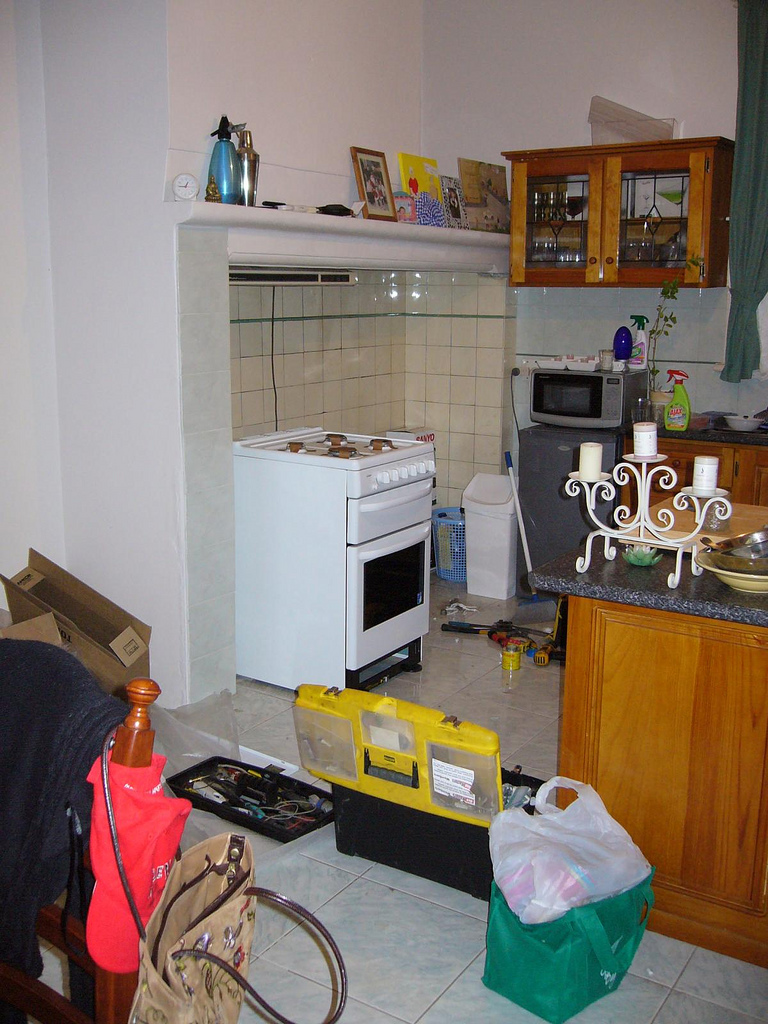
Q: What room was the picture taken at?
A: It was taken at the kitchen.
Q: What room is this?
A: It is a kitchen.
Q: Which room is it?
A: It is a kitchen.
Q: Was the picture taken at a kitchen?
A: Yes, it was taken in a kitchen.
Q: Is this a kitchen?
A: Yes, it is a kitchen.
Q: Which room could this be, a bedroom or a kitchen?
A: It is a kitchen.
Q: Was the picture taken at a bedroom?
A: No, the picture was taken in a kitchen.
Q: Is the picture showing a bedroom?
A: No, the picture is showing a kitchen.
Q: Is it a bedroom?
A: No, it is a kitchen.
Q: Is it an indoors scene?
A: Yes, it is indoors.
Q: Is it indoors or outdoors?
A: It is indoors.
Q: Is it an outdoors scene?
A: No, it is indoors.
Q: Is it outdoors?
A: No, it is indoors.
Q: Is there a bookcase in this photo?
A: No, there are no bookcases.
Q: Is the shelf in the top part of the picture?
A: Yes, the shelf is in the top of the image.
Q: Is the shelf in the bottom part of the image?
A: No, the shelf is in the top of the image.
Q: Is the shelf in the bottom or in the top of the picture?
A: The shelf is in the top of the image.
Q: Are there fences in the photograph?
A: No, there are no fences.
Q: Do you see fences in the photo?
A: No, there are no fences.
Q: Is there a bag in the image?
A: Yes, there is a bag.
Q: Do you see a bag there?
A: Yes, there is a bag.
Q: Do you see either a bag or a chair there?
A: Yes, there is a bag.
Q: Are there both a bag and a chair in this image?
A: Yes, there are both a bag and a chair.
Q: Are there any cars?
A: No, there are no cars.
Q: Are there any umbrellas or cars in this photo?
A: No, there are no cars or umbrellas.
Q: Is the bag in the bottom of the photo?
A: Yes, the bag is in the bottom of the image.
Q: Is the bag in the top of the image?
A: No, the bag is in the bottom of the image.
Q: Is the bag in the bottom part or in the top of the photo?
A: The bag is in the bottom of the image.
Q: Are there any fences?
A: No, there are no fences.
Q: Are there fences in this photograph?
A: No, there are no fences.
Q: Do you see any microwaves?
A: Yes, there is a microwave.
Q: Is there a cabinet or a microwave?
A: Yes, there is a microwave.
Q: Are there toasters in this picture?
A: No, there are no toasters.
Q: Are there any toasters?
A: No, there are no toasters.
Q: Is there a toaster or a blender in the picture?
A: No, there are no toasters or blenders.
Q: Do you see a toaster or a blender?
A: No, there are no toasters or blenders.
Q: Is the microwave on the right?
A: Yes, the microwave is on the right of the image.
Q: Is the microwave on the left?
A: No, the microwave is on the right of the image.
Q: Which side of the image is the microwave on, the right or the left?
A: The microwave is on the right of the image.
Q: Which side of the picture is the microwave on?
A: The microwave is on the right of the image.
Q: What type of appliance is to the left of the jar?
A: The appliance is a stove.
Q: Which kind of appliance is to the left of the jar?
A: The appliance is a stove.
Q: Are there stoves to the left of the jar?
A: Yes, there is a stove to the left of the jar.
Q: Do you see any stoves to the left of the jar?
A: Yes, there is a stove to the left of the jar.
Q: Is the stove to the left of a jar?
A: Yes, the stove is to the left of a jar.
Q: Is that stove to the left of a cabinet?
A: No, the stove is to the left of a jar.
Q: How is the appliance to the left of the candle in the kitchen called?
A: The appliance is a stove.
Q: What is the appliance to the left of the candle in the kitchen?
A: The appliance is a stove.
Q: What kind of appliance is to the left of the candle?
A: The appliance is a stove.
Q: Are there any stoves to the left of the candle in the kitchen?
A: Yes, there is a stove to the left of the candle.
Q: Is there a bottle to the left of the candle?
A: No, there is a stove to the left of the candle.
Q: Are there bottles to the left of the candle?
A: No, there is a stove to the left of the candle.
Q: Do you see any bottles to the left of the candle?
A: No, there is a stove to the left of the candle.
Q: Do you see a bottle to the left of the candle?
A: No, there is a stove to the left of the candle.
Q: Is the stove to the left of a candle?
A: Yes, the stove is to the left of a candle.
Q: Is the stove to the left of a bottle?
A: No, the stove is to the left of a candle.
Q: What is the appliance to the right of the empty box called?
A: The appliance is a stove.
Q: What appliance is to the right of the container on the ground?
A: The appliance is a stove.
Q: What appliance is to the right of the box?
A: The appliance is a stove.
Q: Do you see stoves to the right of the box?
A: Yes, there is a stove to the right of the box.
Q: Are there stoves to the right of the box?
A: Yes, there is a stove to the right of the box.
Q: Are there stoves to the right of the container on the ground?
A: Yes, there is a stove to the right of the box.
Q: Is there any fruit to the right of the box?
A: No, there is a stove to the right of the box.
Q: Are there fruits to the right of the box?
A: No, there is a stove to the right of the box.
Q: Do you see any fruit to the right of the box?
A: No, there is a stove to the right of the box.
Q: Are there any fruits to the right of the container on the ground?
A: No, there is a stove to the right of the box.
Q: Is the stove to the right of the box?
A: Yes, the stove is to the right of the box.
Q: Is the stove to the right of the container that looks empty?
A: Yes, the stove is to the right of the box.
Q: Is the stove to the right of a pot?
A: No, the stove is to the right of the box.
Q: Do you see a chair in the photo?
A: Yes, there is a chair.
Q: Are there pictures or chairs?
A: Yes, there is a chair.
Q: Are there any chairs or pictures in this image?
A: Yes, there is a chair.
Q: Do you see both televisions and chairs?
A: No, there is a chair but no televisions.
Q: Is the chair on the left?
A: Yes, the chair is on the left of the image.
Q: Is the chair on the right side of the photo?
A: No, the chair is on the left of the image.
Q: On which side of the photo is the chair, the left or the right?
A: The chair is on the left of the image.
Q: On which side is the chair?
A: The chair is on the left of the image.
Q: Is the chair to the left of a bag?
A: Yes, the chair is to the left of a bag.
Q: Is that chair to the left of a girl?
A: No, the chair is to the left of a bag.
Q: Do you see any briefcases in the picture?
A: No, there are no briefcases.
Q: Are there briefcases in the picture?
A: No, there are no briefcases.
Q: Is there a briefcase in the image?
A: No, there are no briefcases.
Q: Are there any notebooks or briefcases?
A: No, there are no briefcases or notebooks.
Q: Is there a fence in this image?
A: No, there are no fences.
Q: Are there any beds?
A: No, there are no beds.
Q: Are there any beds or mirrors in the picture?
A: No, there are no beds or mirrors.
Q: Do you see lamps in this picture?
A: No, there are no lamps.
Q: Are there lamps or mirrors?
A: No, there are no lamps or mirrors.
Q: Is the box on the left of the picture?
A: Yes, the box is on the left of the image.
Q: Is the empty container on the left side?
A: Yes, the box is on the left of the image.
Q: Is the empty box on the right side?
A: No, the box is on the left of the image.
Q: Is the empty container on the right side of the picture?
A: No, the box is on the left of the image.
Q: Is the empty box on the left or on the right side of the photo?
A: The box is on the left of the image.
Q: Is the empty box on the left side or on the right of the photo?
A: The box is on the left of the image.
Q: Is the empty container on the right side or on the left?
A: The box is on the left of the image.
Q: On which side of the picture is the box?
A: The box is on the left of the image.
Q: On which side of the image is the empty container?
A: The box is on the left of the image.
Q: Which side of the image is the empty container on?
A: The box is on the left of the image.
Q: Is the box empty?
A: Yes, the box is empty.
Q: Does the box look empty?
A: Yes, the box is empty.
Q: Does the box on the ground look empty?
A: Yes, the box is empty.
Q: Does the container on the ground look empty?
A: Yes, the box is empty.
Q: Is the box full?
A: No, the box is empty.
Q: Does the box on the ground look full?
A: No, the box is empty.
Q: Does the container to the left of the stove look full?
A: No, the box is empty.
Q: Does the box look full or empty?
A: The box is empty.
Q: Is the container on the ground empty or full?
A: The box is empty.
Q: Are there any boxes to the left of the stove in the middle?
A: Yes, there is a box to the left of the stove.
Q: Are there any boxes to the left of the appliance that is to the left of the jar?
A: Yes, there is a box to the left of the stove.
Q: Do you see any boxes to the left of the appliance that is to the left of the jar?
A: Yes, there is a box to the left of the stove.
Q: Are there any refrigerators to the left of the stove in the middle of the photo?
A: No, there is a box to the left of the stove.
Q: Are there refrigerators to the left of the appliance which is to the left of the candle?
A: No, there is a box to the left of the stove.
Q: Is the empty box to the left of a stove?
A: Yes, the box is to the left of a stove.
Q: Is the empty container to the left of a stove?
A: Yes, the box is to the left of a stove.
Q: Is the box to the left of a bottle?
A: No, the box is to the left of a stove.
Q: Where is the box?
A: The box is on the ground.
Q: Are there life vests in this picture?
A: No, there are no life vests.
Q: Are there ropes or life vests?
A: No, there are no life vests or ropes.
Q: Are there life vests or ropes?
A: No, there are no life vests or ropes.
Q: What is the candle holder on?
A: The candle holder is on the counter.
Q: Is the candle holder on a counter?
A: Yes, the candle holder is on a counter.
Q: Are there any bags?
A: Yes, there is a bag.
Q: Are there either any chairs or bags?
A: Yes, there is a bag.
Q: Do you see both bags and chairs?
A: Yes, there are both a bag and a chair.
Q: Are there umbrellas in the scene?
A: No, there are no umbrellas.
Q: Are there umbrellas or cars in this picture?
A: No, there are no umbrellas or cars.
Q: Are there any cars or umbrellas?
A: No, there are no umbrellas or cars.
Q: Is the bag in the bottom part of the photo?
A: Yes, the bag is in the bottom of the image.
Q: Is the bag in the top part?
A: No, the bag is in the bottom of the image.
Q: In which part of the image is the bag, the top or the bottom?
A: The bag is in the bottom of the image.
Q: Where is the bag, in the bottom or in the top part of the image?
A: The bag is in the bottom of the image.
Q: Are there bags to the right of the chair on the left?
A: Yes, there is a bag to the right of the chair.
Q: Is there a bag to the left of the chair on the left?
A: No, the bag is to the right of the chair.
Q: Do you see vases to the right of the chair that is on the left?
A: No, there is a bag to the right of the chair.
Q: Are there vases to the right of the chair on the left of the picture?
A: No, there is a bag to the right of the chair.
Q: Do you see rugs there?
A: No, there are no rugs.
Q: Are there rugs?
A: No, there are no rugs.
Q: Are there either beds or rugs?
A: No, there are no rugs or beds.